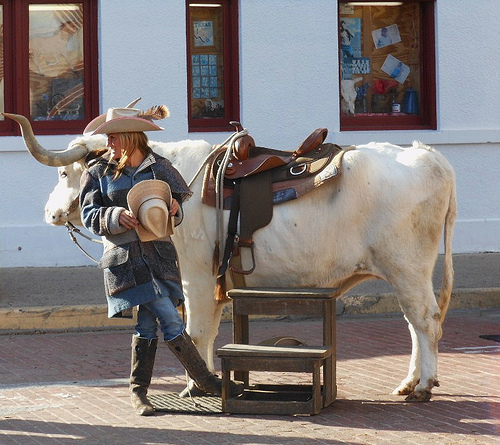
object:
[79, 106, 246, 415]
cowgirl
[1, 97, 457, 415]
steer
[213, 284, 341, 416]
stool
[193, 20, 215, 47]
poster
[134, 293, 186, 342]
jeans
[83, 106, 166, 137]
hat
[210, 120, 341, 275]
saddle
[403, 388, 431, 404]
hoof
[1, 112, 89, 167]
horn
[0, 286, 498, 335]
curb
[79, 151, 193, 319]
coat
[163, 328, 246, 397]
boot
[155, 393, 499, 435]
shadow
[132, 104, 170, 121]
feather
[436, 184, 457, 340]
tail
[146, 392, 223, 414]
grate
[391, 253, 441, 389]
leg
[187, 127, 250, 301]
rope